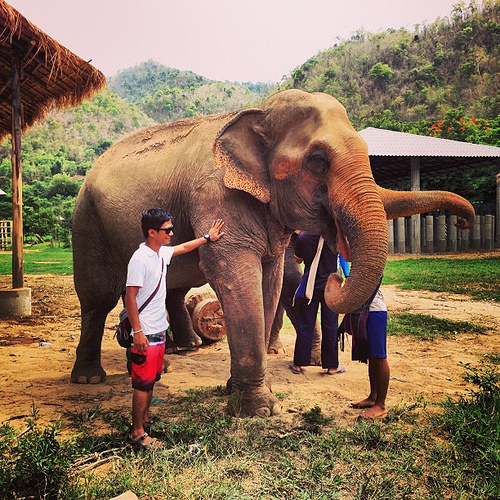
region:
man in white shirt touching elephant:
[113, 205, 227, 457]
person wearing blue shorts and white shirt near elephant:
[318, 200, 394, 425]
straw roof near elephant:
[0, 0, 112, 322]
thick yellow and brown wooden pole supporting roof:
[5, 32, 36, 322]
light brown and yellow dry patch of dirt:
[1, 266, 499, 496]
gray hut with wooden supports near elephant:
[253, 121, 498, 266]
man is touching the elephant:
[118, 203, 240, 325]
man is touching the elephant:
[115, 194, 256, 265]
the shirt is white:
[119, 246, 173, 333]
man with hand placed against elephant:
[67, 87, 389, 455]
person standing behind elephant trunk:
[315, 208, 395, 423]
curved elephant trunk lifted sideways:
[376, 180, 478, 232]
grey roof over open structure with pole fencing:
[359, 120, 496, 257]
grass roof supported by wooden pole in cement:
[2, 4, 104, 321]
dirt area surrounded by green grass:
[4, 241, 494, 495]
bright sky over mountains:
[20, 3, 492, 94]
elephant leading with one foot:
[177, 86, 387, 421]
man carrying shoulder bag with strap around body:
[112, 207, 177, 347]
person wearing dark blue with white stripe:
[285, 225, 342, 377]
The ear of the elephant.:
[214, 110, 278, 197]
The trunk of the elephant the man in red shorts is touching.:
[324, 173, 384, 318]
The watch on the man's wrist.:
[203, 231, 213, 241]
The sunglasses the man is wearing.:
[162, 228, 175, 233]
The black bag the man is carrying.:
[115, 309, 132, 346]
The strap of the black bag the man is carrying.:
[126, 255, 166, 317]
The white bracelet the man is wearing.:
[126, 326, 145, 337]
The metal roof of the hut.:
[358, 118, 499, 172]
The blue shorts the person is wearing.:
[358, 311, 388, 361]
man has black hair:
[143, 189, 178, 236]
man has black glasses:
[151, 219, 178, 239]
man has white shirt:
[88, 231, 173, 325]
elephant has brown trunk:
[269, 142, 420, 317]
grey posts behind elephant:
[390, 206, 490, 261]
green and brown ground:
[336, 371, 433, 497]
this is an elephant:
[23, 43, 430, 448]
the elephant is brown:
[65, 71, 420, 457]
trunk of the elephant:
[318, 140, 410, 351]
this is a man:
[112, 182, 250, 445]